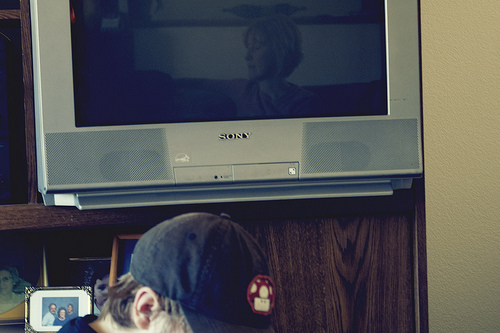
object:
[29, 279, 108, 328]
picture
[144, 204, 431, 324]
entertainment center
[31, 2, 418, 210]
tv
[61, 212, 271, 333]
person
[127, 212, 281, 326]
hat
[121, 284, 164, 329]
ear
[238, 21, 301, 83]
head